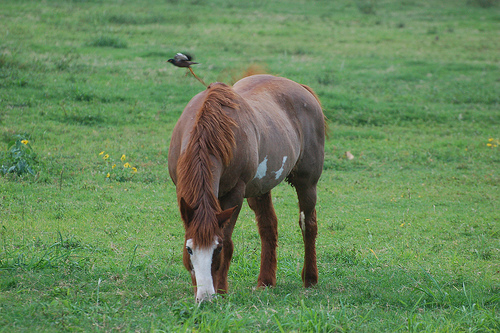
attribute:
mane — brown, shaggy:
[190, 84, 240, 172]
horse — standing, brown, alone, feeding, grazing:
[184, 72, 322, 274]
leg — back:
[291, 181, 332, 305]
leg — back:
[255, 191, 278, 287]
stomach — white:
[246, 152, 294, 198]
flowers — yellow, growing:
[94, 146, 135, 172]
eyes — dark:
[182, 236, 220, 258]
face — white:
[187, 234, 218, 299]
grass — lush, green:
[19, 248, 474, 328]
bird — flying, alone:
[171, 40, 197, 73]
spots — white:
[242, 153, 318, 190]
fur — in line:
[193, 80, 229, 176]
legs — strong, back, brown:
[201, 178, 325, 299]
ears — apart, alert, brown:
[176, 201, 245, 225]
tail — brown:
[303, 77, 335, 137]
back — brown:
[239, 65, 300, 116]